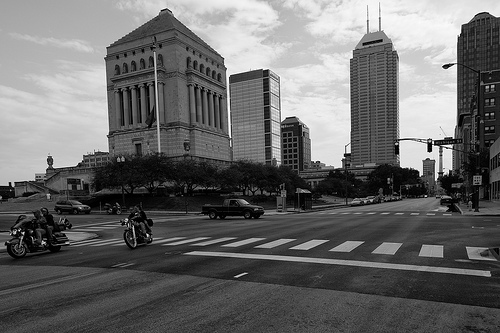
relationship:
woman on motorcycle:
[40, 207, 56, 242] [6, 227, 71, 258]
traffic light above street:
[394, 141, 401, 155] [173, 197, 500, 330]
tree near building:
[94, 159, 156, 194] [107, 7, 233, 170]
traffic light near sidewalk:
[394, 141, 401, 155] [454, 194, 499, 216]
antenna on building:
[366, 4, 370, 35] [350, 32, 399, 175]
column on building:
[189, 84, 197, 123] [107, 7, 233, 170]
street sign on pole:
[434, 138, 462, 146] [397, 137, 481, 212]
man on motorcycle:
[32, 209, 45, 245] [6, 227, 71, 258]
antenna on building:
[378, 2, 382, 33] [350, 32, 399, 175]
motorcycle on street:
[119, 218, 153, 247] [173, 197, 500, 330]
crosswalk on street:
[70, 236, 499, 261] [173, 197, 500, 330]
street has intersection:
[173, 197, 500, 330] [106, 212, 485, 251]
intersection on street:
[106, 212, 485, 251] [173, 197, 500, 330]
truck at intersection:
[202, 197, 265, 219] [106, 212, 485, 251]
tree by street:
[94, 159, 156, 194] [173, 197, 500, 330]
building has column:
[107, 7, 233, 170] [121, 87, 132, 129]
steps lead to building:
[13, 167, 59, 195] [107, 7, 233, 170]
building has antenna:
[350, 32, 399, 175] [366, 4, 370, 35]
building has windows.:
[228, 69, 282, 167] [242, 84, 249, 87]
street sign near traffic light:
[434, 138, 462, 146] [428, 138, 433, 151]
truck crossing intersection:
[202, 197, 265, 219] [106, 212, 485, 251]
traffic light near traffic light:
[394, 141, 401, 155] [428, 138, 433, 151]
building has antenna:
[350, 32, 399, 175] [378, 2, 382, 33]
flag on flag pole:
[144, 105, 157, 127] [152, 44, 162, 158]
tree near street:
[94, 159, 156, 194] [173, 197, 500, 330]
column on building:
[114, 88, 122, 128] [107, 7, 233, 170]